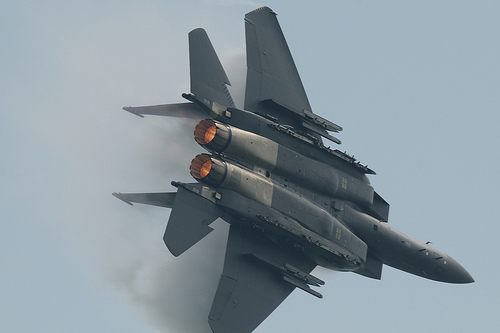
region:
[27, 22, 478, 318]
solid blue background behind black jet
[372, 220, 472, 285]
pointy shape of front of plane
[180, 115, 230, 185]
two ribbed rings with orange light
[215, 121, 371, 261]
gray and black cylinders on either side of body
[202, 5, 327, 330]
triangular shape of wing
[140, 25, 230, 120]
perpendicular tail pieces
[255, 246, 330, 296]
clips on raised panels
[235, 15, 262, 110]
angled flaps on back of wings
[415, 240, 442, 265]
tiny curls on top of body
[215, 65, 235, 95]
sharp barb on tail wing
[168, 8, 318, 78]
hands of the plane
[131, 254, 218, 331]
smoke from the plane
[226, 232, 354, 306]
a object jointed to plane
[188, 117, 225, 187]
two whole for smoke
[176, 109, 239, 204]
smoke emission from whole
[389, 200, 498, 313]
front part of rocket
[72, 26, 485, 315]
a big rocket in air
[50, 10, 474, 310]
a rocket flying in sky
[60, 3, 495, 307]
a rocket going speedly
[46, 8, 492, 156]
a clear view of sky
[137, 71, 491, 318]
this is a rocket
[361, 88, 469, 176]
the sky is clear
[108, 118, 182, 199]
the sky is clear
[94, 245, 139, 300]
the sky is clear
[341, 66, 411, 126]
the sky is clear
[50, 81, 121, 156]
the sky is clear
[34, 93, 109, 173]
the sky is clear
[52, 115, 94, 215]
the sky is clear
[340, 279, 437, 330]
the sky is clear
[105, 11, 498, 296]
the jet is gray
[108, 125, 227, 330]
a gray cloud of smoke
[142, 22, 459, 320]
Jet in the air.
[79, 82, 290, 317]
Smoke from the jet.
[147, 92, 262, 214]
Lights on the jet.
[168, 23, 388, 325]
Wings on the jet.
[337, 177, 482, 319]
Front of the jet.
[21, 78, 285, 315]
Sky with jet in it.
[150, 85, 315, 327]
Dark cloud of smoke.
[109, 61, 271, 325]
Grey smoke from the jet.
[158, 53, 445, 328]
Engines on the jet.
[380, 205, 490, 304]
Wheels on the jet.